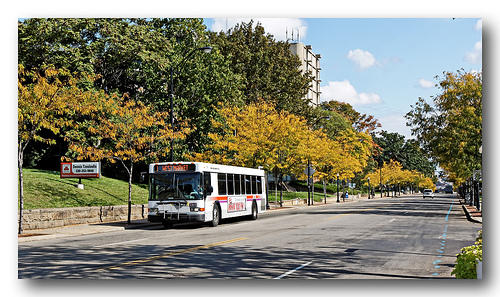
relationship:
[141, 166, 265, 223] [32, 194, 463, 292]
bus on road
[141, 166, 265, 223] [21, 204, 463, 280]
bus on road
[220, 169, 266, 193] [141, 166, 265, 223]
windows of bus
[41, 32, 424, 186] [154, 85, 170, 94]
trees with leaves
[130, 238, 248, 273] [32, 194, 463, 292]
lines on road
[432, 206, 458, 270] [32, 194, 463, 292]
lines on road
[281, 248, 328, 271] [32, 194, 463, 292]
lines on road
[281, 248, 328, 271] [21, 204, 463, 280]
lines on road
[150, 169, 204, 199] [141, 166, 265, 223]
windshield of bus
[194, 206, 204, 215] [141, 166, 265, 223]
headlight on bus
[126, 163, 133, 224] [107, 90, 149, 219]
trunk of tree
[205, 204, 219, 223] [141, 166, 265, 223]
wheel of bus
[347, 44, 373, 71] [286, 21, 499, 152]
cloud in sky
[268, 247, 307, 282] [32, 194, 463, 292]
stripe on road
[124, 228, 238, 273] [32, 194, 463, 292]
stripe on road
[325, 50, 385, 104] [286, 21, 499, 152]
clouds in sky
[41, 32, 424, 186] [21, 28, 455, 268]
trees in picture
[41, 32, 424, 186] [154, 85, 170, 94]
trees have leaves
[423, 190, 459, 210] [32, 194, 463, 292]
cars on road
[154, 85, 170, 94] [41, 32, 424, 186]
leaves on trees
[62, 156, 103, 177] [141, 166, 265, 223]
sign next to bus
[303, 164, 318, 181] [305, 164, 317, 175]
back of sign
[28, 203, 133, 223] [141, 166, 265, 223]
wall near bus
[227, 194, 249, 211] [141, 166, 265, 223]
ad on side of bus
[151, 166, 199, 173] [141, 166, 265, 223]
board on bus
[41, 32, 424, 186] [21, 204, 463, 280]
trees line road